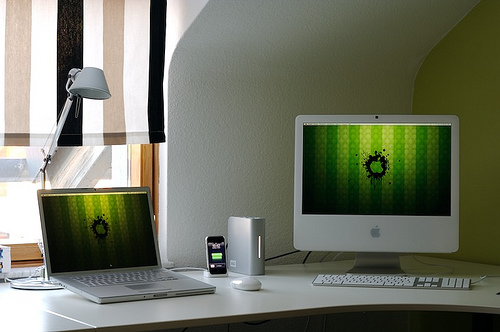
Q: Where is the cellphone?
A: Between the desktop and laptop.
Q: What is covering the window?
A: Window shade.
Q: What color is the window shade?
A: Black white and tan.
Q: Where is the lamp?
A: Above the laptop.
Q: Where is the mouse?
A: In front of the cell phone.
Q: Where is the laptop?
A: In front of the window.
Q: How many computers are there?
A: Two.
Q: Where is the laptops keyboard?
A: Attached.